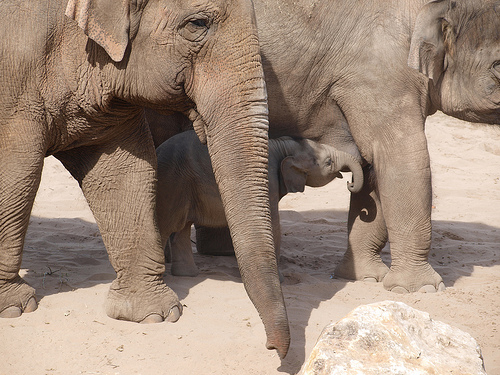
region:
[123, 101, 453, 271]
baby elephant in between adults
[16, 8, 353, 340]
the elephant is gray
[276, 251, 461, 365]
rock in front of elephants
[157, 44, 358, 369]
elephant has a long trunk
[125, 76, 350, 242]
shadow on baby elephant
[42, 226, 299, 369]
elephants standing on sand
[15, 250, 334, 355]
the sand is beige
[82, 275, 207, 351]
elephant has gray nails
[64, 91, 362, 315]
elephant has wrinkly skin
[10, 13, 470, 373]
the elephants are all standing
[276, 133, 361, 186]
a baby elephant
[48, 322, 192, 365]
the sand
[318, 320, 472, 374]
a big rock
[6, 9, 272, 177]
a big elephant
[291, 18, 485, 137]
a big elephant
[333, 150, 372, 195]
the baby elephants trunk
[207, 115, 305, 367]
the big elephants trunk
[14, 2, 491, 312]
the elephants are standing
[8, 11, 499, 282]
the elephants are grey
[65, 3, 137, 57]
an elephants ear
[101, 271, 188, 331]
the foot of an elephant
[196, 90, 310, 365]
the trunk of an elephant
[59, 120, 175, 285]
the leg of an elephant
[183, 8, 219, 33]
the eye of an elephant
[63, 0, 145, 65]
the ear of an elephant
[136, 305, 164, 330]
the toe of an elephant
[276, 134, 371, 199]
the head of a baby elephant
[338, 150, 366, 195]
the trunk of a baby elephant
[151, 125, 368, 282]
a gray baby elephant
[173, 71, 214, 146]
the mouth of an elephant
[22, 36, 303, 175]
the elephant has wrinkles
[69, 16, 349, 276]
the elephant has wrinkles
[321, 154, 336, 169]
the eye of a baby elephant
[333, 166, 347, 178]
the mouth of a baby elephant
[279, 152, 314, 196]
the ear of a baby elephant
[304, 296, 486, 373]
a rock on the ground